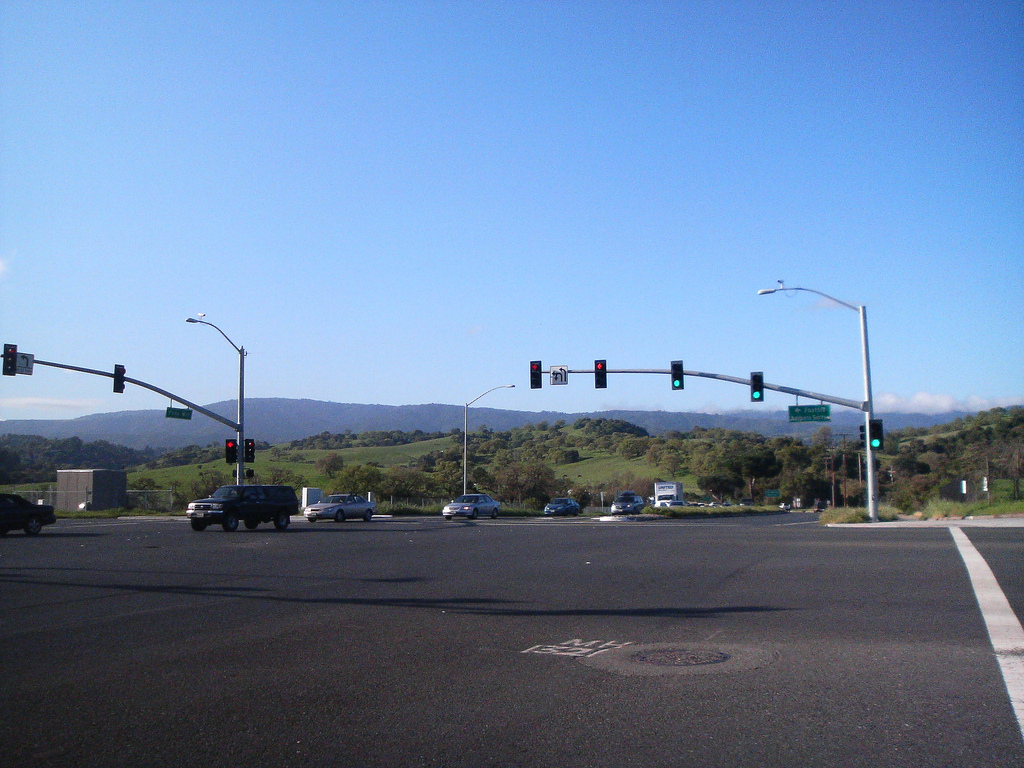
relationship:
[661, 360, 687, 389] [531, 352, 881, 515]
signal light on post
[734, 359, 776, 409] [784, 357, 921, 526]
signal light on post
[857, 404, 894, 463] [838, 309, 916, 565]
signal light on post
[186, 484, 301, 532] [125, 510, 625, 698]
car driving down road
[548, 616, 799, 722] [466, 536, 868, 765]
marking near manhole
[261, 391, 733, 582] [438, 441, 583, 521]
hills covered with trees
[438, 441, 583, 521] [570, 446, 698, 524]
trees and grass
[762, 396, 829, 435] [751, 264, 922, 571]
street sign on top of pole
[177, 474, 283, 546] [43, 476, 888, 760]
car on a street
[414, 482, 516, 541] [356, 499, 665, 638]
car on a street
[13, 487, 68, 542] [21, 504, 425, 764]
car on a street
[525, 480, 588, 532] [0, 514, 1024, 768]
car on a road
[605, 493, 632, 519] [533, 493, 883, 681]
car on a street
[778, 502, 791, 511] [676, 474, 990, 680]
car on a street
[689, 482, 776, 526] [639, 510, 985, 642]
car on a street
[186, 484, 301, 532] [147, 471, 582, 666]
car driving down road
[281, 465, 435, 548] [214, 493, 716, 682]
car driving down road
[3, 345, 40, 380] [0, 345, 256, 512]
traffic light on pole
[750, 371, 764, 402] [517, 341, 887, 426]
signal light on pole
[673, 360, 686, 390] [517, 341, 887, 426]
signal light on pole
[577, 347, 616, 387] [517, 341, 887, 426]
traffic light on pole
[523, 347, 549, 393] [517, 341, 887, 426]
traffic light on pole